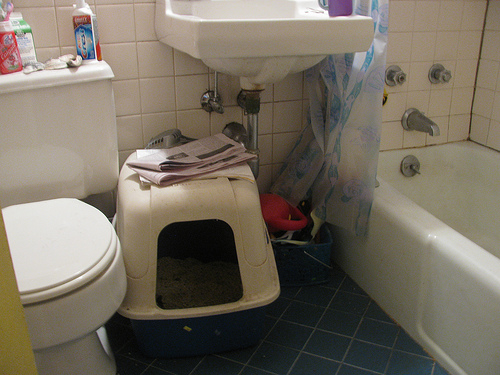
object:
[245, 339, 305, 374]
tile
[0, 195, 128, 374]
toilet seat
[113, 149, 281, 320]
box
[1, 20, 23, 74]
container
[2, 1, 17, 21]
toothbrushes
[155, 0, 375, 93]
sink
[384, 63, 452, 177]
fixtures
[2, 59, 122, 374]
toilet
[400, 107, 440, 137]
silver faucet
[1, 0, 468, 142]
wall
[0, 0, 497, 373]
bathroom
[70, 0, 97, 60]
toothpaste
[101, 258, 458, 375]
blue tile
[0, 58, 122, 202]
tank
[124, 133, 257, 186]
newspapers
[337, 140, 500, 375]
bathtub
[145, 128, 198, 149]
scooper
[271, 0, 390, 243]
curtain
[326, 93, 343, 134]
pattern